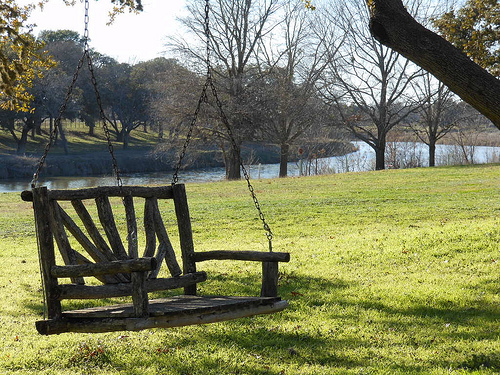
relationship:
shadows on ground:
[43, 267, 335, 324] [33, 171, 445, 372]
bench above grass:
[20, 182, 289, 330] [0, 189, 473, 373]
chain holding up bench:
[169, 2, 278, 246] [20, 182, 289, 330]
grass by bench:
[339, 199, 481, 364] [20, 182, 289, 330]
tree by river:
[286, 1, 446, 169] [0, 139, 499, 194]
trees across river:
[0, 1, 60, 115] [2, 137, 497, 174]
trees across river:
[31, 29, 91, 144] [2, 137, 497, 174]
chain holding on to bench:
[172, 0, 273, 250] [20, 182, 289, 330]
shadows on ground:
[301, 277, 497, 374] [2, 190, 483, 355]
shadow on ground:
[293, 272, 470, 374] [354, 247, 470, 372]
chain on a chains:
[172, 0, 273, 250] [28, 1, 148, 265]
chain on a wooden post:
[172, 0, 273, 250] [37, 172, 197, 195]